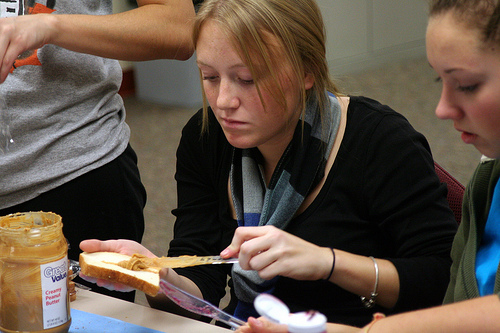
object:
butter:
[0, 209, 213, 331]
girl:
[78, 0, 457, 333]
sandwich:
[77, 247, 159, 296]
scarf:
[224, 89, 341, 331]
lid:
[250, 292, 331, 333]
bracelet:
[360, 256, 380, 306]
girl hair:
[189, 0, 347, 156]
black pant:
[0, 125, 147, 301]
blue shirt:
[442, 159, 500, 305]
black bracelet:
[323, 247, 338, 280]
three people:
[0, 0, 500, 333]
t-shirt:
[0, 0, 134, 208]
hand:
[219, 224, 328, 282]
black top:
[122, 52, 499, 331]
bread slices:
[78, 252, 161, 298]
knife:
[139, 254, 238, 268]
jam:
[161, 281, 213, 314]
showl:
[0, 0, 500, 333]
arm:
[219, 223, 398, 306]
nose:
[435, 82, 464, 120]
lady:
[234, 0, 500, 333]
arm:
[0, 0, 198, 80]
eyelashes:
[199, 74, 262, 85]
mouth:
[218, 116, 249, 127]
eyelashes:
[432, 74, 482, 93]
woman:
[229, 0, 499, 333]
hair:
[427, 0, 499, 49]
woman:
[80, 0, 448, 333]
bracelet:
[372, 312, 384, 326]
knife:
[158, 279, 243, 329]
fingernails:
[220, 248, 232, 257]